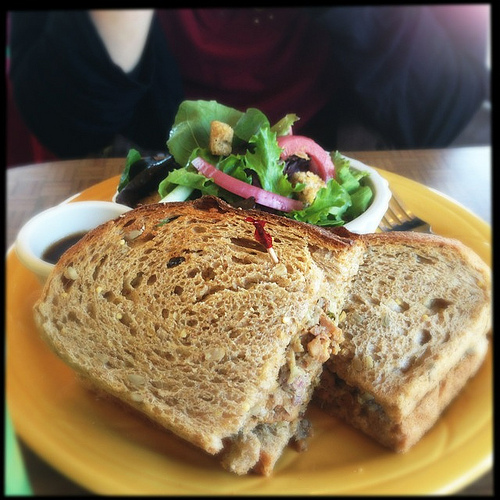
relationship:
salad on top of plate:
[114, 97, 394, 235] [11, 168, 490, 491]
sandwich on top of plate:
[34, 201, 489, 479] [11, 168, 490, 491]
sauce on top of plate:
[41, 229, 88, 265] [11, 168, 490, 491]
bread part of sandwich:
[314, 227, 490, 454] [34, 201, 489, 479]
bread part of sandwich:
[32, 202, 364, 476] [34, 201, 489, 479]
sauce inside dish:
[41, 229, 88, 265] [17, 193, 133, 279]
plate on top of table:
[11, 168, 490, 491] [10, 146, 490, 495]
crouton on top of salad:
[210, 120, 233, 157] [114, 97, 394, 235]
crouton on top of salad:
[293, 170, 328, 208] [114, 97, 394, 235]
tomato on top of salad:
[276, 134, 338, 183] [114, 97, 394, 235]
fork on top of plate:
[376, 190, 434, 233] [11, 168, 490, 491]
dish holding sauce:
[17, 193, 133, 279] [41, 229, 88, 265]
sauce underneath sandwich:
[41, 229, 88, 265] [34, 201, 489, 479]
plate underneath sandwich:
[11, 168, 490, 491] [34, 201, 489, 479]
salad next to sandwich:
[114, 97, 394, 235] [34, 201, 489, 479]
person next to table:
[9, 10, 489, 167] [10, 146, 490, 495]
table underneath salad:
[10, 146, 490, 495] [114, 97, 394, 235]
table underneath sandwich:
[10, 146, 490, 495] [34, 201, 489, 479]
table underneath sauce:
[10, 146, 490, 495] [41, 229, 88, 265]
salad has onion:
[114, 97, 394, 235] [189, 156, 307, 216]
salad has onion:
[114, 97, 394, 235] [159, 183, 195, 204]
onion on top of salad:
[189, 156, 307, 216] [114, 97, 394, 235]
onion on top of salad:
[159, 183, 195, 204] [114, 97, 394, 235]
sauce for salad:
[41, 229, 88, 265] [114, 97, 394, 235]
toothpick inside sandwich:
[246, 210, 278, 265] [34, 201, 489, 479]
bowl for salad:
[326, 151, 392, 236] [114, 97, 394, 235]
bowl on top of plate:
[326, 151, 392, 236] [11, 168, 490, 491]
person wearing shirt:
[9, 10, 489, 167] [165, 12, 337, 133]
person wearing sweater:
[9, 10, 489, 167] [11, 12, 488, 159]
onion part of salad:
[189, 156, 307, 216] [114, 97, 394, 235]